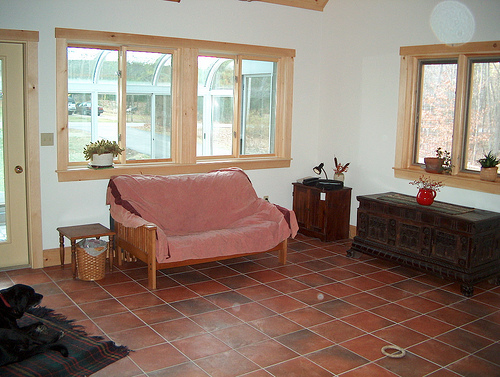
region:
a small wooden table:
[54, 217, 113, 269]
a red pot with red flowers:
[408, 175, 443, 205]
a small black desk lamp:
[310, 157, 332, 189]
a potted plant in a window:
[421, 144, 448, 174]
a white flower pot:
[81, 124, 120, 185]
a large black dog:
[1, 272, 60, 352]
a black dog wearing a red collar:
[1, 274, 53, 318]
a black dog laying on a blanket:
[0, 275, 125, 373]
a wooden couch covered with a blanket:
[115, 181, 287, 293]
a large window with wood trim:
[34, 43, 308, 184]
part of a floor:
[319, 245, 374, 322]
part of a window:
[221, 92, 241, 108]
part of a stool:
[83, 220, 93, 228]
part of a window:
[217, 110, 222, 145]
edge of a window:
[236, 48, 283, 147]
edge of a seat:
[201, 233, 221, 252]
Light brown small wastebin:
[75, 242, 112, 284]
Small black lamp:
[311, 155, 343, 187]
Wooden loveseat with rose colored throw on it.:
[105, 165, 305, 290]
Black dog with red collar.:
[0, 275, 70, 357]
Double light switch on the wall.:
[40, 130, 51, 145]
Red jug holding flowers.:
[410, 175, 441, 205]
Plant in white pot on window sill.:
[82, 135, 122, 169]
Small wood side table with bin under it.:
[53, 222, 122, 280]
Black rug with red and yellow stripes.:
[5, 310, 127, 372]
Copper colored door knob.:
[14, 160, 24, 181]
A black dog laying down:
[2, 272, 64, 364]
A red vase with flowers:
[410, 168, 447, 210]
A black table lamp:
[313, 159, 340, 189]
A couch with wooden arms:
[104, 165, 304, 286]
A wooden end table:
[52, 221, 117, 278]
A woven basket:
[73, 236, 112, 286]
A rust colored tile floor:
[115, 282, 405, 359]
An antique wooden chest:
[344, 188, 497, 292]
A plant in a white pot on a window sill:
[67, 135, 162, 177]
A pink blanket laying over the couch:
[107, 163, 295, 264]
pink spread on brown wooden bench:
[116, 170, 292, 258]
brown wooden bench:
[113, 224, 155, 271]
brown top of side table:
[56, 221, 116, 240]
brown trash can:
[84, 253, 105, 279]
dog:
[13, 284, 43, 321]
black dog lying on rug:
[1, 282, 47, 343]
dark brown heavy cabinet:
[368, 200, 478, 268]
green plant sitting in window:
[78, 136, 118, 170]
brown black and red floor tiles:
[310, 265, 417, 336]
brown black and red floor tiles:
[142, 305, 298, 362]